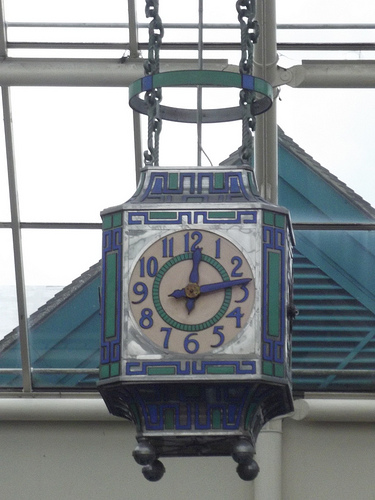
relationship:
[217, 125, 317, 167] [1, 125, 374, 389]
top piece of a roof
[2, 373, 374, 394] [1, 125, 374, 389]
bottom piece of roof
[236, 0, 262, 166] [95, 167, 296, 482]
chain supporting a aztec design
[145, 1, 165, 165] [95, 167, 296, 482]
chain supporting a aztec design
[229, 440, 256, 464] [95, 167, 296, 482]
ball on bottom of a aztec design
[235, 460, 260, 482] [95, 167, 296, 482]
ball on bottom of a aztec design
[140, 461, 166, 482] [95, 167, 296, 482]
ball on bottom of a aztec design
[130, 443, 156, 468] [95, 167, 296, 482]
ball on bottom of a aztec design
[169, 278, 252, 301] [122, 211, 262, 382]
hand on clock face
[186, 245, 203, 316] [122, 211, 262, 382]
hand on clock face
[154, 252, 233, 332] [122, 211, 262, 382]
circle on clock face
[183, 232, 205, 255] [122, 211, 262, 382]
arabic number on clock face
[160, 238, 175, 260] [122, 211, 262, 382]
arabic number on clock face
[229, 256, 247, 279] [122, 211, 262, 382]
arabic number on clock face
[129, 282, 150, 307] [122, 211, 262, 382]
arabic number on clock face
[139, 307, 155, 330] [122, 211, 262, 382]
arabic number on clock face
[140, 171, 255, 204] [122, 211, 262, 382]
decoration above clock face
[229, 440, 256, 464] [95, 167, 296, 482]
silver ball on bottom of an aztec design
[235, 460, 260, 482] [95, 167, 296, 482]
silver ball on bottom of an aztec design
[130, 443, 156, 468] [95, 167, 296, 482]
silver ball on bottom of an aztec design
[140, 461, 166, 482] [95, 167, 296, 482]
silver ball on bottom of an aztec design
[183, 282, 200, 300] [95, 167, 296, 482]
flower in middle of a aztec design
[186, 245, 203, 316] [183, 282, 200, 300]
clock hand with a flower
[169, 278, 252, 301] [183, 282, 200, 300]
clock hand with a flower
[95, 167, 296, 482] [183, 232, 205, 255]
aztec design with blue number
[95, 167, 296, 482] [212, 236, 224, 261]
aztec design with a blue number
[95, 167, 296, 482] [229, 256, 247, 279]
aztec design with a blue number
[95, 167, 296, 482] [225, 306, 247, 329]
aztec design with a blue number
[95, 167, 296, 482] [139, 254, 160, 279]
aztec design with a blue number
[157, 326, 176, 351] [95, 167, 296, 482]
blue number on aztec design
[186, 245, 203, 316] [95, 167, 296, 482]
hand on aztec design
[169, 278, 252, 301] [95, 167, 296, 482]
hand on aztec design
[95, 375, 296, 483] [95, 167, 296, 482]
bottom part of aztec design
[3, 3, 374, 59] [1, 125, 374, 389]
sky above house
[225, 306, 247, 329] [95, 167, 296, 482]
number 4 on aztec design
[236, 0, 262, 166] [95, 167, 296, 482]
chain holding aztec design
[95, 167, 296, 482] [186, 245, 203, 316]
aztec design with a little hand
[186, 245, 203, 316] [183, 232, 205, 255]
little hand pointing at twelve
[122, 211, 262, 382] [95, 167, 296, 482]
face of a aztec design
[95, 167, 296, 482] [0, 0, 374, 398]
aztec design hanging from roof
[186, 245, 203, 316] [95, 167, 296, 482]
hand of a aztec design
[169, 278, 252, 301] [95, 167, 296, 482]
hand of a aztec design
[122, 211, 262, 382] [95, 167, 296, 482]
middle of a aztec design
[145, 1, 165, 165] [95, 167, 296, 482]
chain over aztec design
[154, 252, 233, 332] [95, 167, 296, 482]
green ring on aztec design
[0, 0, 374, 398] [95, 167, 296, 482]
roof behind aztec design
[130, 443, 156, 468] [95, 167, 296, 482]
metal ball under aztec design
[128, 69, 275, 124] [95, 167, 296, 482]
ring over aztec design